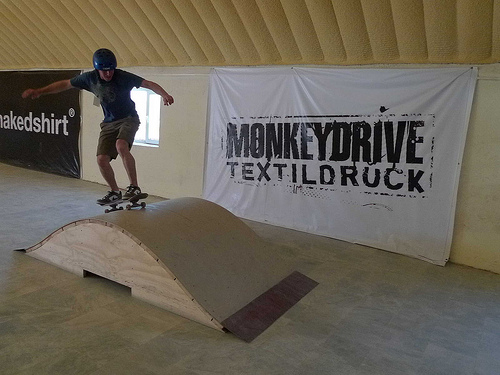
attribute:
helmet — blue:
[89, 45, 121, 85]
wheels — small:
[123, 195, 150, 209]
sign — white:
[200, 63, 477, 265]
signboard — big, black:
[0, 68, 81, 179]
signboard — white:
[198, 65, 478, 257]